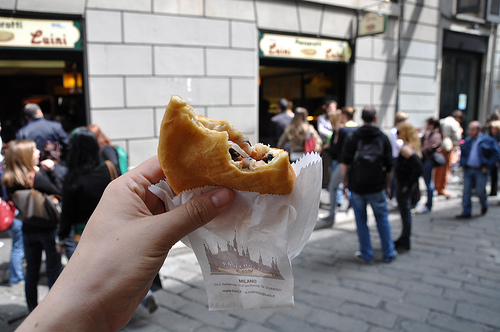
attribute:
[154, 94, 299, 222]
empanada — half eaten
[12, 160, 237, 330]
person — standing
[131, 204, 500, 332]
street — grey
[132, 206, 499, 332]
cobblestones — grey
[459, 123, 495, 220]
person — walking, male, bald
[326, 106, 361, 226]
person — walking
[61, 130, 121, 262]
person — walking, female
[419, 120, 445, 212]
person — walking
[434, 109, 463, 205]
person — walking, male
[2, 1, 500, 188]
building — concrete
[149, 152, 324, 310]
bag — white, paper, small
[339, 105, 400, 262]
man — standing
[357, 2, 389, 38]
sign — overhead, hanging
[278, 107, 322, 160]
person — woman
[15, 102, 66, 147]
person — male, tall, balding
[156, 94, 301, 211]
food — pizza pocket, partially eaten, bitten, pita sandwich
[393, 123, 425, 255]
woman — standing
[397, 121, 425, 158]
hair — blonde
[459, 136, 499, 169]
coat — blue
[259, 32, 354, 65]
sign — hanging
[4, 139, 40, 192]
hair — light brown, long, brown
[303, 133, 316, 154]
bag — red, hanging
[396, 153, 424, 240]
clothing — black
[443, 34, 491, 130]
door — black, glass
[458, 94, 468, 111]
sign — small, blue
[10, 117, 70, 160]
coat — black, dark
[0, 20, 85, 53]
sign — partially visible, on left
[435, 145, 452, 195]
pants — orange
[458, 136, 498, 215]
clothes — blue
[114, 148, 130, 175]
backpack — green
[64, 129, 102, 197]
hair — long, dark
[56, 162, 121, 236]
shirt — dark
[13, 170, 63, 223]
bag — large